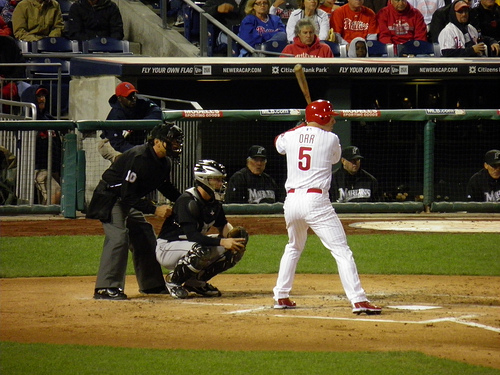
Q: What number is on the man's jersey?
A: 5.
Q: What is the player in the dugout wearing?
A: Red hat.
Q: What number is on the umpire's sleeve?
A: 10.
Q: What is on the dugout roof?
A: Advertisements.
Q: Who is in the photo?
A: Baseball player.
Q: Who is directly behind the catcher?
A: Umpire.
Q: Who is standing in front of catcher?
A: Batter.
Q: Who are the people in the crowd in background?
A: Spectators.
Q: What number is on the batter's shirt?
A: 5.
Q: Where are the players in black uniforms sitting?
A: Dugout.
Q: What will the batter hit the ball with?
A: Bat.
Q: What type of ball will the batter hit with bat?
A: Baseball.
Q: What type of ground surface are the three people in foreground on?
A: Dirt.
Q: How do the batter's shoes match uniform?
A: They are red.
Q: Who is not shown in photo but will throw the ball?
A: Pitcher.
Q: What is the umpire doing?
A: Watching the play.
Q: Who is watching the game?
A: The audience.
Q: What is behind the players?
A: A green fence.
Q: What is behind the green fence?
A: A metal fence.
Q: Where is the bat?
A: In the guys hands.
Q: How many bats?
A: 1.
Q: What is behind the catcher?
A: Ump.